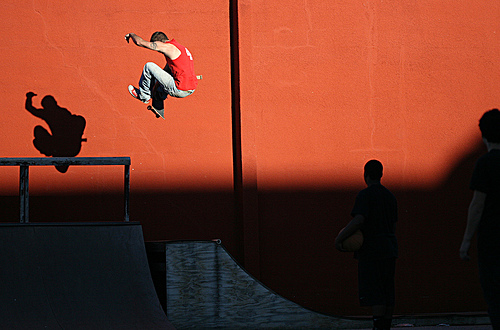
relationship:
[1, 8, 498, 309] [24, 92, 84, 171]
wall has shadow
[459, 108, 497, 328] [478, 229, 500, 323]
man wearing jeans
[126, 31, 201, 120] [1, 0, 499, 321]
skateboarder in air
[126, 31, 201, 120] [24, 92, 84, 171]
skateboarder has shadow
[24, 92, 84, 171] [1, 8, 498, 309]
shadow on wall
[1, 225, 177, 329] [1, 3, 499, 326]
ramp at skatepark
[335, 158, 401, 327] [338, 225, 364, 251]
boy holding ball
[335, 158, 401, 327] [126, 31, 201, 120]
boy watching skateboarder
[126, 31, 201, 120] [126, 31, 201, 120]
skateboarder doing a trick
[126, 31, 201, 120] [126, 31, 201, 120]
skateboarder doing a stunt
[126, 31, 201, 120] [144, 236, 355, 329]
skateboarder above ramp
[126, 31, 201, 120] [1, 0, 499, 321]
man in air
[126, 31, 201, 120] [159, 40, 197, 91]
man has shirt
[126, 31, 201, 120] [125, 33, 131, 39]
man wearing watch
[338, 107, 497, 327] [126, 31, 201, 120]
2 people are watching skateboarder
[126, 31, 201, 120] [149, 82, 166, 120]
man holding skateboard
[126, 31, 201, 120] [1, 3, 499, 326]
skateboarder at skatepark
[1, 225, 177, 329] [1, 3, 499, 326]
ramp in a park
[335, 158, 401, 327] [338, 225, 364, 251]
man has ball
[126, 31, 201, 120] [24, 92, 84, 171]
skateboard has shadow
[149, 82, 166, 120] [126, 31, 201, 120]
skateboard doing stunt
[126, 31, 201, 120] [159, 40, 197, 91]
skateboard wearing shirt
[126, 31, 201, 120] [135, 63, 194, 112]
skateboard wearing jeans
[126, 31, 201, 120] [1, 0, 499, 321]
skateboarder catching air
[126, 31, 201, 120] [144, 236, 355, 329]
skateboarder catching air off of halfpipe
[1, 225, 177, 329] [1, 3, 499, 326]
ramp are in park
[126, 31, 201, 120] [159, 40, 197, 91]
boy wearing shirt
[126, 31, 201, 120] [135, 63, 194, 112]
boy has pants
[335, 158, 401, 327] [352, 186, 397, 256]
spectator wearing t-shirt